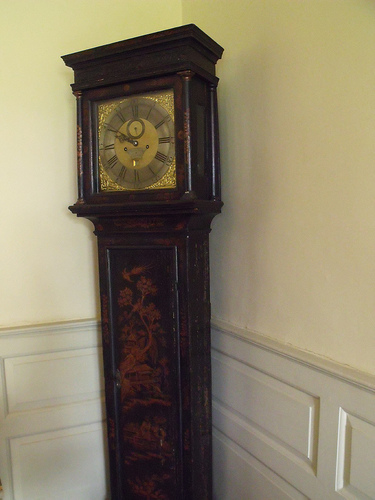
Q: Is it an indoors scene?
A: Yes, it is indoors.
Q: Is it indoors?
A: Yes, it is indoors.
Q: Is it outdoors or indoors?
A: It is indoors.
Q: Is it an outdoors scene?
A: No, it is indoors.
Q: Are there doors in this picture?
A: Yes, there is a door.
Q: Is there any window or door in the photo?
A: Yes, there is a door.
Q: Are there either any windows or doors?
A: Yes, there is a door.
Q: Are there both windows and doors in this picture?
A: No, there is a door but no windows.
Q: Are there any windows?
A: No, there are no windows.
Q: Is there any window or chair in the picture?
A: No, there are no windows or chairs.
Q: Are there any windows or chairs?
A: No, there are no windows or chairs.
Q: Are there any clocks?
A: Yes, there is a clock.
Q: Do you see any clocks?
A: Yes, there is a clock.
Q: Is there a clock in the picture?
A: Yes, there is a clock.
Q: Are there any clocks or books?
A: Yes, there is a clock.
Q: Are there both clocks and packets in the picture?
A: No, there is a clock but no packets.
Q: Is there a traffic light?
A: No, there are no traffic lights.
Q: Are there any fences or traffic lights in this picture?
A: No, there are no traffic lights or fences.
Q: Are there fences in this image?
A: No, there are no fences.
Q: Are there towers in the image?
A: No, there are no towers.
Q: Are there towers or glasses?
A: No, there are no towers or glasses.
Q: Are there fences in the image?
A: No, there are no fences.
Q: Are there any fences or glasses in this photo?
A: No, there are no fences or glasses.